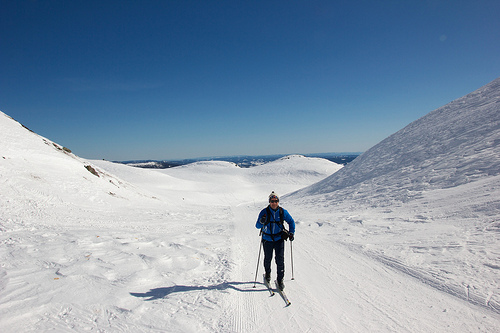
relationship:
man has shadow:
[255, 189, 297, 293] [127, 279, 277, 303]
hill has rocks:
[1, 107, 126, 231] [47, 136, 103, 182]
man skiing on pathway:
[255, 189, 297, 293] [213, 172, 325, 325]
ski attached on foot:
[273, 275, 293, 308] [277, 278, 285, 291]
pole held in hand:
[286, 237, 297, 283] [289, 230, 294, 242]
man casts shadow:
[255, 189, 297, 293] [127, 279, 277, 303]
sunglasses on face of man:
[268, 196, 280, 204] [255, 189, 297, 293]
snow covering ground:
[1, 76, 500, 326] [1, 76, 500, 326]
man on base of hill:
[255, 189, 297, 293] [1, 107, 126, 231]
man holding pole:
[255, 189, 297, 293] [286, 237, 297, 283]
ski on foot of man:
[273, 275, 293, 308] [255, 189, 297, 293]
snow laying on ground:
[1, 76, 500, 326] [1, 76, 500, 326]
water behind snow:
[106, 152, 363, 168] [1, 76, 500, 326]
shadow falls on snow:
[127, 279, 277, 303] [1, 76, 500, 326]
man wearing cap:
[255, 189, 297, 293] [266, 188, 281, 200]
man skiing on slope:
[255, 189, 297, 293] [273, 73, 499, 317]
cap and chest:
[266, 188, 281, 200] [265, 206, 286, 226]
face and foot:
[269, 196, 281, 210] [277, 278, 285, 291]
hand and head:
[289, 230, 294, 242] [266, 191, 281, 211]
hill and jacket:
[1, 107, 126, 231] [254, 206, 296, 244]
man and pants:
[255, 189, 297, 293] [260, 238, 287, 283]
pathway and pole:
[213, 172, 325, 325] [286, 237, 297, 283]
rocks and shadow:
[47, 136, 103, 182] [127, 279, 277, 303]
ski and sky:
[273, 275, 293, 308] [0, 1, 499, 163]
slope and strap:
[273, 73, 499, 317] [278, 206, 283, 230]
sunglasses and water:
[268, 196, 280, 204] [106, 152, 363, 168]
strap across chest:
[278, 206, 283, 230] [265, 206, 286, 226]